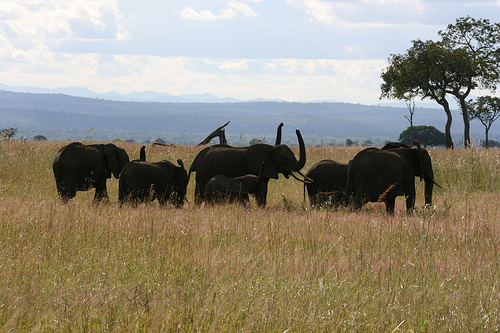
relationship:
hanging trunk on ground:
[418, 164, 453, 206] [5, 193, 497, 320]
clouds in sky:
[1, 1, 493, 102] [1, 1, 499, 101]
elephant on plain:
[190, 129, 314, 208] [0, 140, 499, 331]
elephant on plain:
[194, 139, 316, 199] [21, 130, 470, 309]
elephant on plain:
[347, 149, 437, 218] [0, 202, 498, 332]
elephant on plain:
[190, 129, 314, 208] [0, 202, 498, 332]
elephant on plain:
[118, 158, 188, 210] [0, 202, 498, 332]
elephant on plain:
[49, 144, 136, 206] [0, 202, 498, 332]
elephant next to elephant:
[53, 141, 146, 206] [117, 154, 188, 213]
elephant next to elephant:
[117, 154, 188, 213] [190, 129, 314, 208]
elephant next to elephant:
[190, 129, 314, 208] [210, 168, 272, 213]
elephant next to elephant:
[190, 129, 314, 208] [343, 142, 448, 214]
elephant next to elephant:
[210, 168, 272, 213] [343, 142, 448, 214]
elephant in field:
[53, 141, 146, 206] [2, 135, 497, 330]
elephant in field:
[117, 154, 188, 213] [2, 135, 497, 330]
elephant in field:
[190, 129, 314, 208] [2, 135, 497, 330]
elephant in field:
[210, 168, 272, 213] [2, 135, 497, 330]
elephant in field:
[343, 142, 448, 214] [2, 135, 497, 330]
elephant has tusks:
[190, 129, 314, 208] [288, 173, 315, 185]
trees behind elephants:
[374, 21, 488, 148] [51, 120, 444, 217]